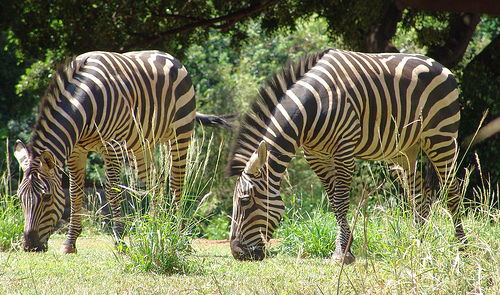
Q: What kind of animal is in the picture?
A: Zebra.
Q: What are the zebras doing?
A: Eating.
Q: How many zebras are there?
A: Two.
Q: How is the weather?
A: Sunny.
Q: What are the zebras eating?
A: Grass.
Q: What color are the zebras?
A: Black and white.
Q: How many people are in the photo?
A: None.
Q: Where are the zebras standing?
A: In a field.